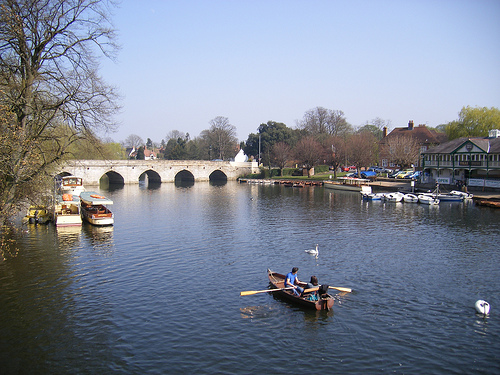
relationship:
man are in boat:
[283, 266, 305, 296] [267, 268, 335, 311]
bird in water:
[306, 243, 320, 253] [0, 181, 499, 374]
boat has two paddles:
[267, 268, 335, 311] [240, 284, 353, 296]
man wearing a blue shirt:
[285, 267, 304, 295] [285, 272, 297, 286]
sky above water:
[0, 0, 500, 145] [0, 181, 499, 374]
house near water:
[376, 120, 440, 171] [0, 181, 499, 374]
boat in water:
[267, 268, 335, 311] [0, 181, 499, 374]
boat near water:
[267, 268, 335, 311] [0, 181, 499, 374]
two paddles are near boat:
[240, 284, 353, 296] [267, 268, 335, 311]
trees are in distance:
[122, 104, 500, 177] [0, 0, 500, 207]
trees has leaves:
[262, 140, 299, 176] [0, 0, 44, 263]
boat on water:
[267, 268, 335, 311] [0, 181, 499, 374]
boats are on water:
[361, 185, 469, 204] [0, 181, 499, 374]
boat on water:
[22, 195, 53, 225] [0, 181, 499, 374]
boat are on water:
[22, 202, 49, 226] [0, 181, 499, 374]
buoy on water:
[476, 300, 490, 314] [0, 181, 499, 374]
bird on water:
[306, 243, 320, 253] [0, 181, 499, 374]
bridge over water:
[49, 160, 260, 189] [0, 181, 499, 374]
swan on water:
[306, 243, 320, 253] [0, 181, 499, 374]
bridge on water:
[49, 160, 260, 189] [0, 181, 499, 374]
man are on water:
[283, 266, 305, 296] [0, 181, 499, 374]